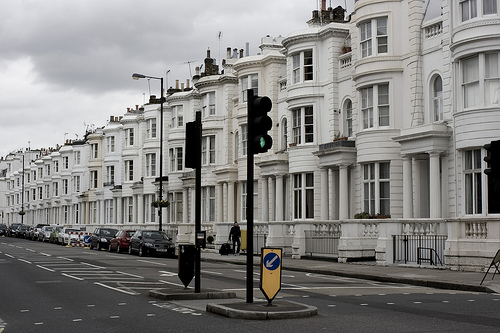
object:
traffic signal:
[234, 89, 279, 304]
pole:
[242, 161, 256, 311]